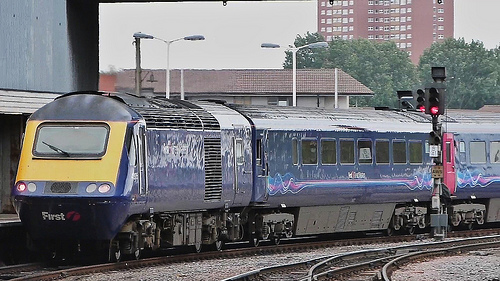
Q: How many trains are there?
A: 1.